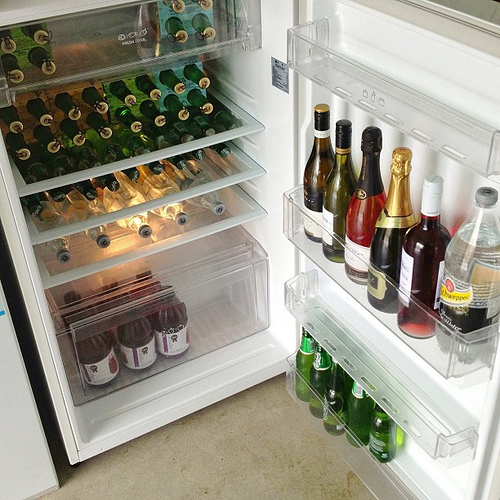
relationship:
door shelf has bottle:
[282, 182, 499, 380] [302, 103, 336, 243]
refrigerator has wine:
[4, 1, 496, 491] [398, 217, 451, 340]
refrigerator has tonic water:
[4, 1, 496, 491] [436, 223, 499, 363]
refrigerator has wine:
[4, 1, 496, 491] [343, 188, 388, 279]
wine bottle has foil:
[369, 147, 418, 315] [384, 147, 415, 218]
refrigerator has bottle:
[4, 1, 496, 491] [345, 380, 374, 447]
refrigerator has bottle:
[4, 1, 496, 491] [308, 343, 333, 420]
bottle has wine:
[397, 175, 450, 340] [398, 217, 451, 340]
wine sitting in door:
[398, 217, 451, 340] [295, 1, 499, 499]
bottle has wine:
[345, 125, 388, 284] [343, 188, 388, 279]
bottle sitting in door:
[345, 125, 388, 284] [295, 1, 499, 499]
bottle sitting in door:
[302, 103, 336, 243] [295, 1, 499, 499]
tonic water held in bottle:
[436, 223, 499, 363] [434, 184, 499, 364]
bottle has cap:
[434, 184, 499, 364] [474, 186, 499, 204]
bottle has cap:
[397, 175, 450, 340] [421, 173, 444, 218]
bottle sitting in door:
[308, 343, 333, 420] [295, 1, 499, 499]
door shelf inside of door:
[285, 17, 499, 179] [295, 1, 499, 499]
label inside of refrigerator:
[270, 56, 291, 95] [4, 1, 496, 491]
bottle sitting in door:
[345, 380, 374, 447] [295, 1, 499, 499]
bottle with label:
[434, 184, 499, 364] [438, 278, 474, 307]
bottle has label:
[397, 175, 450, 340] [397, 245, 415, 308]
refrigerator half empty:
[4, 1, 496, 491] [342, 24, 471, 100]